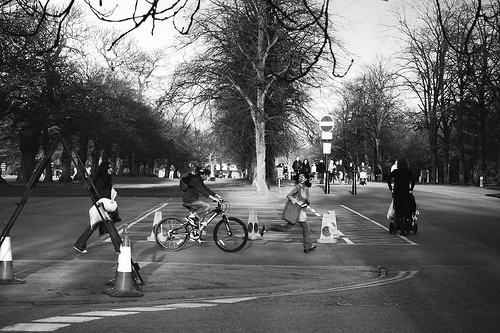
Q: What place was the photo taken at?
A: It was taken at the street.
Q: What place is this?
A: It is a street.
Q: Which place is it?
A: It is a street.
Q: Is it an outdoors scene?
A: Yes, it is outdoors.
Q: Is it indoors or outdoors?
A: It is outdoors.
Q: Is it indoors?
A: No, it is outdoors.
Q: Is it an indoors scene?
A: No, it is outdoors.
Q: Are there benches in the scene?
A: No, there are no benches.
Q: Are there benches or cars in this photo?
A: No, there are no benches or cars.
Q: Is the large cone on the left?
A: Yes, the cone is on the left of the image.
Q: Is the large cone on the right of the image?
A: No, the cone is on the left of the image.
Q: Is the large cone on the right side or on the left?
A: The traffic cone is on the left of the image.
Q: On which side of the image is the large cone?
A: The traffic cone is on the left of the image.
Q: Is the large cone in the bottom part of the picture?
A: Yes, the cone is in the bottom of the image.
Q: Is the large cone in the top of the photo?
A: No, the traffic cone is in the bottom of the image.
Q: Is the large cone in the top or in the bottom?
A: The traffic cone is in the bottom of the image.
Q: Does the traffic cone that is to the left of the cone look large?
A: Yes, the cone is large.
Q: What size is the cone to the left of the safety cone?
A: The traffic cone is large.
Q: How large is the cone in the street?
A: The cone is large.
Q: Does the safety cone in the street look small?
A: No, the traffic cone is large.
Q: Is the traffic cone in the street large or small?
A: The cone is large.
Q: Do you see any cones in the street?
A: Yes, there is a cone in the street.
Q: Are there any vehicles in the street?
A: No, there is a cone in the street.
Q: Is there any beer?
A: Yes, there is beer.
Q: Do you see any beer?
A: Yes, there is beer.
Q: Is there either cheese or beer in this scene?
A: Yes, there is beer.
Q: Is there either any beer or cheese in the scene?
A: Yes, there is beer.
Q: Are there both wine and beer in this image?
A: No, there is beer but no wine.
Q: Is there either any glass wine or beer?
A: Yes, there is glass beer.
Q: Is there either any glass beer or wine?
A: Yes, there is glass beer.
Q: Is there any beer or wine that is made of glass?
A: Yes, the beer is made of glass.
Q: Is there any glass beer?
A: Yes, there is beer that is made of glass.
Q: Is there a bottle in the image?
A: No, there are no bottles.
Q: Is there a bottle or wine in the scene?
A: No, there are no bottles or wine.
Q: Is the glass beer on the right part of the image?
A: Yes, the beer is on the right of the image.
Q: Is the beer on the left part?
A: No, the beer is on the right of the image.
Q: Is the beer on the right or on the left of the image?
A: The beer is on the right of the image.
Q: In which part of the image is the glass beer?
A: The beer is on the right of the image.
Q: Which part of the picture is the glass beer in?
A: The beer is on the right of the image.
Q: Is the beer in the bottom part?
A: Yes, the beer is in the bottom of the image.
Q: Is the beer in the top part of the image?
A: No, the beer is in the bottom of the image.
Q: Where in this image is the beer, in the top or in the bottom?
A: The beer is in the bottom of the image.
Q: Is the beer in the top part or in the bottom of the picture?
A: The beer is in the bottom of the image.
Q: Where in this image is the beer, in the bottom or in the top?
A: The beer is in the bottom of the image.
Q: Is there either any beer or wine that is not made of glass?
A: No, there is beer but it is made of glass.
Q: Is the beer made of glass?
A: Yes, the beer is made of glass.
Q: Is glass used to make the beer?
A: Yes, the beer is made of glass.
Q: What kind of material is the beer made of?
A: The beer is made of glass.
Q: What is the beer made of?
A: The beer is made of glass.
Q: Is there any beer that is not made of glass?
A: No, there is beer but it is made of glass.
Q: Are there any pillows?
A: No, there are no pillows.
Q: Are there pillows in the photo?
A: No, there are no pillows.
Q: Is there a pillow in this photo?
A: No, there are no pillows.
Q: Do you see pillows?
A: No, there are no pillows.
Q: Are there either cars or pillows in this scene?
A: No, there are no pillows or cars.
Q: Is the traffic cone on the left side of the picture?
A: Yes, the traffic cone is on the left of the image.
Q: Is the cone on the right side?
A: No, the cone is on the left of the image.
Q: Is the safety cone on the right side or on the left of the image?
A: The safety cone is on the left of the image.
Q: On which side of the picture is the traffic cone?
A: The traffic cone is on the left of the image.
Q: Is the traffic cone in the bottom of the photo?
A: Yes, the traffic cone is in the bottom of the image.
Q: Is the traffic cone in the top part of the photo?
A: No, the traffic cone is in the bottom of the image.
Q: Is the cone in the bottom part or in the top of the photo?
A: The cone is in the bottom of the image.